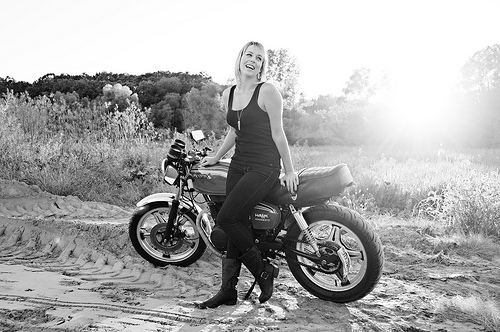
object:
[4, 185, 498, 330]
road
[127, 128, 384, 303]
motorcycle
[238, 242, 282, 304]
boots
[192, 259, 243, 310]
boots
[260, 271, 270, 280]
buckle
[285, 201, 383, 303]
black tire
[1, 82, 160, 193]
bushes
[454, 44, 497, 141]
trees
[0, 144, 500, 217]
roadside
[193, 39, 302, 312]
lady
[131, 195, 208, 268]
tire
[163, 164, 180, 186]
mirror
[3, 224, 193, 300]
tire tracks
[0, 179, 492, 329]
dirt road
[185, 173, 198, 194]
handle bars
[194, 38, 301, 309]
woman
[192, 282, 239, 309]
feet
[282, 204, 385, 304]
tire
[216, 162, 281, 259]
pants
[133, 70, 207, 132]
trees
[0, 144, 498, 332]
field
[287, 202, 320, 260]
shock